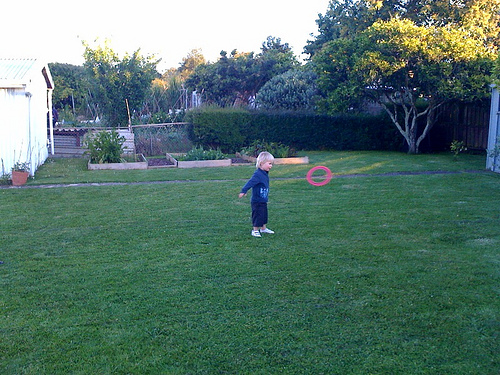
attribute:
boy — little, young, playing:
[237, 148, 279, 241]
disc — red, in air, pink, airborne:
[303, 162, 331, 187]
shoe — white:
[250, 225, 263, 240]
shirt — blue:
[243, 167, 270, 204]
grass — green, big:
[1, 148, 499, 373]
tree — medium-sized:
[315, 16, 499, 154]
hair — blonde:
[257, 150, 275, 168]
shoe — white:
[262, 225, 274, 234]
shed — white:
[1, 58, 66, 183]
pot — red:
[14, 167, 31, 185]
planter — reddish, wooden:
[87, 153, 148, 169]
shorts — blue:
[248, 198, 269, 228]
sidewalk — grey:
[0, 169, 494, 191]